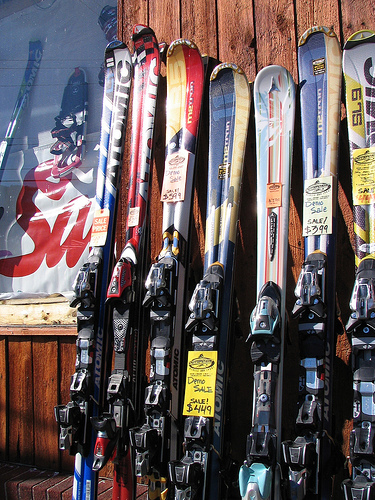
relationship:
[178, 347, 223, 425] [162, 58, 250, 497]
tag on skis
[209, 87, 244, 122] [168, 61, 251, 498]
11 on ski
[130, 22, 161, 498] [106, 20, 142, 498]
stripes on ski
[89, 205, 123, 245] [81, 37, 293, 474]
675 on ski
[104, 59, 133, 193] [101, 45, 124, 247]
atomic on ski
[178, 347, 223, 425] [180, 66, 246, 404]
tag on ski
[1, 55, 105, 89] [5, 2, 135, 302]
utility lines reflected in window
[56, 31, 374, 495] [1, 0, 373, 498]
skies lined on wall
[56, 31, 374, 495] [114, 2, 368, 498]
skies lined on wall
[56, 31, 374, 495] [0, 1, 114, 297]
skies lined next to window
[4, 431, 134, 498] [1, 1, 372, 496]
brick trim at bottom of building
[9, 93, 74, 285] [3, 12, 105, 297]
white sign in window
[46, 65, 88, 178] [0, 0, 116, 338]
snowshoe hanging in window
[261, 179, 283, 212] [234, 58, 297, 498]
price tag on ski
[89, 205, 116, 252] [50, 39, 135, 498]
price tag on ski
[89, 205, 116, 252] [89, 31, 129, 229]
price tag on ski